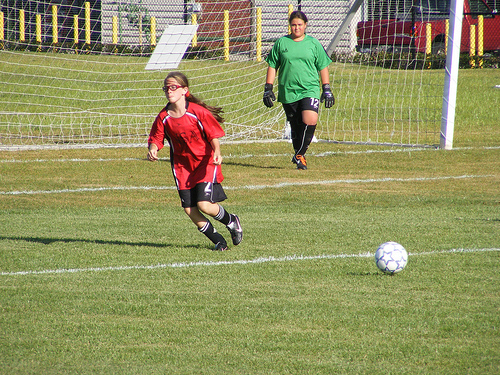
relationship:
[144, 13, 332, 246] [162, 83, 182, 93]
girl in eye glass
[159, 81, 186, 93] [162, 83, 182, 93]
girl in eye glass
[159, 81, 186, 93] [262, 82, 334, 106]
girl in gloves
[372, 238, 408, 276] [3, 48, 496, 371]
ball on field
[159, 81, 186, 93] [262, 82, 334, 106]
girl i gloves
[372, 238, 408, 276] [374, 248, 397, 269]
ball has stars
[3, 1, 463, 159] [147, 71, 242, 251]
goal net behind girl